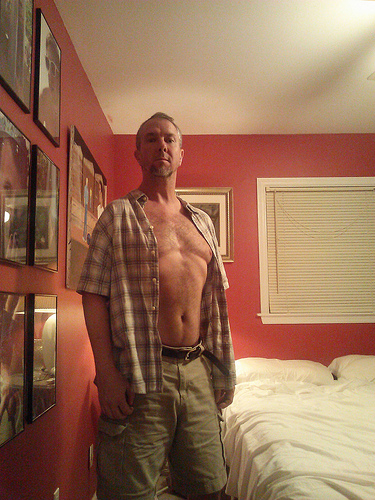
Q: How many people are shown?
A: One.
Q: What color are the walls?
A: Red.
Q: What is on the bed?
A: Sheets.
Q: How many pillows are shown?
A: Two.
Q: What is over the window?
A: Blinds.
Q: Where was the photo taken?
A: In a bedroom.